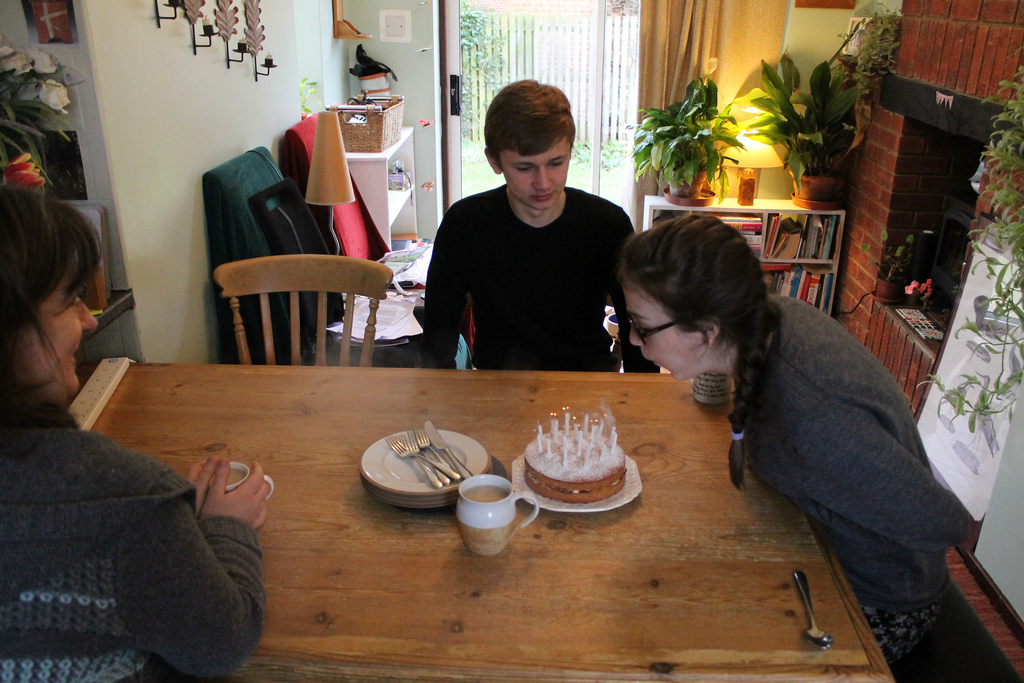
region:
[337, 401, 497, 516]
silverware on top of a platter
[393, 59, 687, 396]
boy wearing a long sleeved shirt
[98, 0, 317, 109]
candle holder on the wall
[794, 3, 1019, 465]
a red brick fireplace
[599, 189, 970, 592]
woman with braided hair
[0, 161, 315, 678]
woman holding a mug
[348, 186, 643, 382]
boy has black shirt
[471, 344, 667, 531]
brown and white cake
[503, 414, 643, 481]
white candles on cake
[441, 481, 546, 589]
small mug next to cake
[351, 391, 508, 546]
white plates on table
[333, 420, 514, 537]
silverware on white plates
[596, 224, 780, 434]
girl has brown hair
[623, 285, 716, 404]
girl is wearing glasses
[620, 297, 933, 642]
girl has grey shirt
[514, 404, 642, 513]
Half frosted birthday cake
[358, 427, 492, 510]
Stack of plates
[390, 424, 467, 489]
Stack of forks and knife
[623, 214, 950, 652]
Birthday girl blowing out her candles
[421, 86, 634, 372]
Teenage boy in a black shirt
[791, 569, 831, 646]
Clean silver spoon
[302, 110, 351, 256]
Slim lamp with shade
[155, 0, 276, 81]
Wall sconces with candles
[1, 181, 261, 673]
Woman holding coffee cup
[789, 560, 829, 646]
silver spoon on corner of table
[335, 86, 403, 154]
brown wicker basket on white cabinet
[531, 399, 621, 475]
paritally lit birthday candles on cake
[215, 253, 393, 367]
empty brown chair at table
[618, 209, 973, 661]
girl in glasses blowing out candles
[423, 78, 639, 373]
boy in black shirt watching girl blow out candles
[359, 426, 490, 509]
stack of white plates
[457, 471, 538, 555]
beige and white coffee cup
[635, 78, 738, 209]
smaller potted plant near window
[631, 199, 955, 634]
woman blowing out candles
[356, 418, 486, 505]
white plates stacked on the table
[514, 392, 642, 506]
cake with white candles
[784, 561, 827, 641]
spoon on the table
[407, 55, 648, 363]
boy wearing black shirt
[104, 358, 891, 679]
wood table the cake is on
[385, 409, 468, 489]
forks and knives on the plates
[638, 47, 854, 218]
plants in brown pots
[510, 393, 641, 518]
A small birthday cake with candles.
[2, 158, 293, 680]
A woman sitting with a cup of coffee.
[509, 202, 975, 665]
A girl blowing out candles on a cake.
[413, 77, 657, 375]
A boy in black.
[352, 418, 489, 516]
Stacked plates and silverware.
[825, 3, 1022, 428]
A red brick fireplace.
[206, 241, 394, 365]
An empty wooden chair.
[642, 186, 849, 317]
A white bookcase.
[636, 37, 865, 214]
Two lush potted plants.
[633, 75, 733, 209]
plant in a pot on the shelf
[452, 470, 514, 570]
mug of coffee on the table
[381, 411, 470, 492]
forks and knives on top of the plates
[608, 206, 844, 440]
girl blowing out her birthday candles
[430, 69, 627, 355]
guy wearing a black shirt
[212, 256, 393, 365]
brown wooden chair in front of the table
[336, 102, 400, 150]
brown basket on the shelf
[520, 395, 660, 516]
a birthday cake on plate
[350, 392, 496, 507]
a stack of white plates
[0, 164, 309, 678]
a lady that is smiling